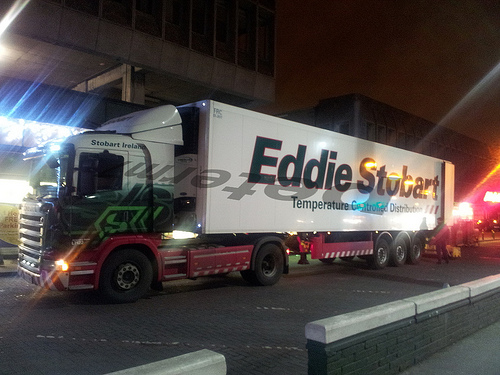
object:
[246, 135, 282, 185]
letter e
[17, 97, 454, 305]
truck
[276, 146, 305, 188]
d's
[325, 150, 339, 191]
i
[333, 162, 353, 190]
e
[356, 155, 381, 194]
s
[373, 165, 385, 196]
t's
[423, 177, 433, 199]
r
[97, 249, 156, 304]
5 wheels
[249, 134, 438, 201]
eddie stobart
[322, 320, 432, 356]
wall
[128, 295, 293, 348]
street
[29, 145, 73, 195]
windshield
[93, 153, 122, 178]
mirror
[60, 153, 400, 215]
reflection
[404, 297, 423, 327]
lines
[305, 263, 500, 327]
wall edge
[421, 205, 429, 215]
gray square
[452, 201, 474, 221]
lights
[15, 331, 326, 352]
lines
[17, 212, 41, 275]
large grill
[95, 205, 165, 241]
logo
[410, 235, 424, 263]
wheel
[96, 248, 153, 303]
tire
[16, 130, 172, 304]
cab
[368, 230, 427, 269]
set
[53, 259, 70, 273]
illuminated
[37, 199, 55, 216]
headlights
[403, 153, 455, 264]
rear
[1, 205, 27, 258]
sign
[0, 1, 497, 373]
photo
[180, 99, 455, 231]
trailer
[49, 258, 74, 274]
lights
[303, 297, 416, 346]
cement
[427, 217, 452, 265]
man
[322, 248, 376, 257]
stripes